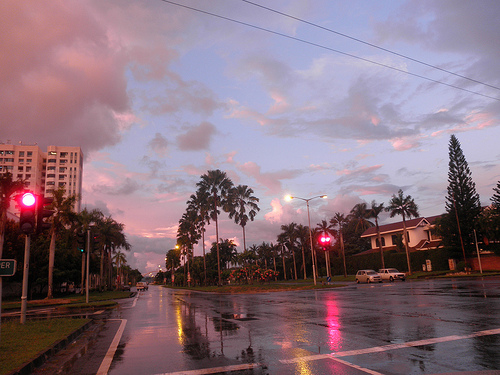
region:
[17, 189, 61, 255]
red street light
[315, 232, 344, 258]
red street light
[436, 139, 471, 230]
tall green tree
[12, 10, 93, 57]
white clouds in blue sky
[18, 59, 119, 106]
white clouds in blue sky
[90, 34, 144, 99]
white clouds in blue sky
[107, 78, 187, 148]
white clouds in blue sky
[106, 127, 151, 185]
white clouds in blue sky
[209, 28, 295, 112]
white clouds in blue sky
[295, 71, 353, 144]
white clouds in blue sky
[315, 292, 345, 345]
light on the street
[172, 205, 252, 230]
palm trees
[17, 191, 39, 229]
a street light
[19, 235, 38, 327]
a pole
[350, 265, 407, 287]
cars on the street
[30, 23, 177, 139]
white clouds in the sky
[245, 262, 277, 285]
flowers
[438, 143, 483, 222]
a green tree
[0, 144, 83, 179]
a tall white building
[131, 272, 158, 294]
a car on the street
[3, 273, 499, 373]
wet, highly reflective pavement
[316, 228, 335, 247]
very bright red light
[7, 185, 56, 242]
black traffic light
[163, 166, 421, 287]
group of many palm trees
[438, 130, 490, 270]
very tall evergreen tree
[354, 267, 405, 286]
two parked cars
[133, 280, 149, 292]
car turning onto road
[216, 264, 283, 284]
plants with orange flowers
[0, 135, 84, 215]
part of white building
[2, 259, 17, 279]
part of green sign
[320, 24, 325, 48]
Two power cables across the street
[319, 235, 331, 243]
Two red traffic lights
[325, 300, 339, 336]
Reflection of lights on the road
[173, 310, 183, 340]
Reflection of a yellow light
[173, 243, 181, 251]
A yellow street lamp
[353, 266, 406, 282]
Cars waiting for lights to turn green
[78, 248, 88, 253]
A green light on a pole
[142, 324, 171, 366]
A wet road surface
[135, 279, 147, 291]
A vehicle turning into the road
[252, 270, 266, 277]
Flower bush on the road island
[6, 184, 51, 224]
red street light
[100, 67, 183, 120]
white clouds in blue sky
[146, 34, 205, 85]
white clouds in blue sky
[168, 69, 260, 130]
white clouds in blue sky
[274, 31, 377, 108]
white clouds in blue sky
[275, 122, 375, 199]
white clouds in blue sky